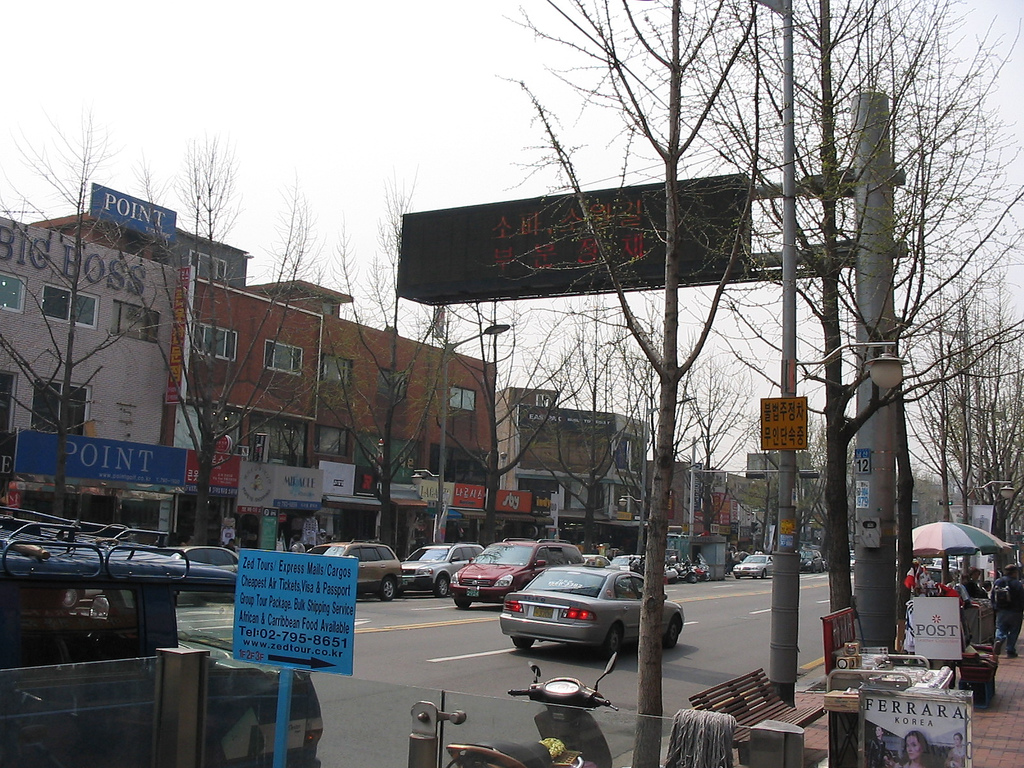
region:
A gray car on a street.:
[502, 562, 689, 651]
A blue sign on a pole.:
[230, 546, 357, 763]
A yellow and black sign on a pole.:
[757, 386, 814, 462]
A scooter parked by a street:
[449, 645, 664, 759]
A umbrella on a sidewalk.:
[910, 520, 1009, 588]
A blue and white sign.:
[5, 430, 190, 500]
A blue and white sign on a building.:
[5, 432, 189, 483]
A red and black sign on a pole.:
[392, 89, 925, 641]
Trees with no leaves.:
[515, 9, 1022, 756]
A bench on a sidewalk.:
[694, 667, 835, 745]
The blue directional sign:
[226, 548, 370, 685]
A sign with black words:
[224, 540, 371, 676]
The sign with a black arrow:
[219, 540, 387, 684]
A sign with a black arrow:
[232, 537, 366, 668]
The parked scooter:
[432, 651, 626, 765]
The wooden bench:
[681, 662, 831, 754]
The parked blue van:
[5, 500, 399, 761]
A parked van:
[1, 502, 362, 758]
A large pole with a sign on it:
[849, 88, 897, 646]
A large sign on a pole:
[405, 177, 753, 295]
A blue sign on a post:
[225, 547, 359, 674]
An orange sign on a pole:
[753, 401, 814, 452]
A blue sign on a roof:
[86, 181, 182, 239]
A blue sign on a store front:
[11, 427, 192, 482]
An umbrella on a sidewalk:
[906, 522, 999, 555]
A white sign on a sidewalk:
[911, 591, 962, 656]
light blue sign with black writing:
[226, 549, 360, 762]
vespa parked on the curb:
[450, 647, 625, 762]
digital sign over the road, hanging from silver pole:
[383, 91, 900, 641]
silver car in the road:
[495, 563, 680, 659]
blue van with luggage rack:
[4, 509, 322, 766]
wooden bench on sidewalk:
[691, 674, 822, 742]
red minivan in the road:
[449, 541, 582, 605]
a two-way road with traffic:
[190, 566, 854, 759]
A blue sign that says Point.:
[8, 420, 195, 507]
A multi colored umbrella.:
[885, 502, 1013, 583]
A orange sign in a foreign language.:
[749, 388, 813, 455]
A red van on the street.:
[439, 528, 594, 611]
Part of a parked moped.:
[424, 651, 627, 766]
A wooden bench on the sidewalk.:
[682, 664, 835, 759]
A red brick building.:
[174, 269, 514, 491]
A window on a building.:
[3, 267, 30, 303]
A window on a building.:
[38, 288, 84, 330]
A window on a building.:
[101, 291, 141, 334]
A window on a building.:
[193, 318, 235, 354]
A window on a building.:
[258, 334, 296, 373]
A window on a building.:
[324, 345, 382, 391]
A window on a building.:
[378, 359, 405, 397]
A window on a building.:
[455, 378, 485, 410]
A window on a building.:
[40, 370, 113, 422]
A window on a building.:
[312, 425, 369, 465]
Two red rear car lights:
[492, 586, 601, 626]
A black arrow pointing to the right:
[256, 633, 336, 676]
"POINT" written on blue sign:
[1, 412, 194, 498]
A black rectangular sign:
[387, 155, 758, 308]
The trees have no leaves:
[498, 0, 1011, 762]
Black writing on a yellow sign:
[744, 383, 817, 461]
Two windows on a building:
[172, 305, 308, 385]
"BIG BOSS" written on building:
[0, 213, 155, 312]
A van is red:
[437, 525, 586, 609]